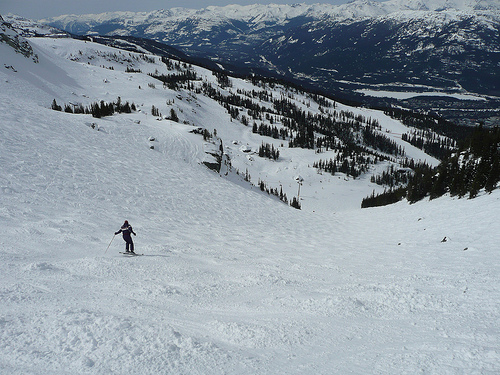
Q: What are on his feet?
A: Skis.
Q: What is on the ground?
A: Snow.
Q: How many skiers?
A: 1.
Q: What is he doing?
A: Skiing.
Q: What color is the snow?
A: White.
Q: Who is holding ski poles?
A: The man.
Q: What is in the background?
A: Mountains.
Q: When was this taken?
A: Daytime.